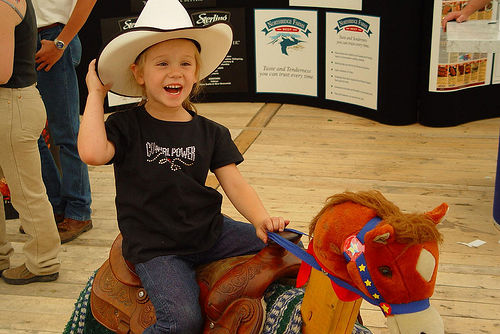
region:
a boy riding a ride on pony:
[62, 1, 471, 332]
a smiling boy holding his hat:
[68, 1, 270, 196]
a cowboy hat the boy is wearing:
[91, 3, 236, 58]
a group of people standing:
[3, 0, 86, 285]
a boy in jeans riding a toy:
[73, 23, 438, 329]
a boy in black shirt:
[73, 22, 305, 324]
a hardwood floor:
[278, 138, 405, 183]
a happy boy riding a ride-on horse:
[56, 5, 460, 332]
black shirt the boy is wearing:
[106, 108, 231, 258]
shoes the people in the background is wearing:
[3, 208, 93, 298]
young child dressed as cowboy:
[76, 2, 285, 332]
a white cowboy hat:
[93, 0, 235, 105]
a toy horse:
[69, 191, 448, 331]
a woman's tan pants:
[2, 85, 63, 277]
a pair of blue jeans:
[33, 23, 95, 222]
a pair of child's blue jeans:
[130, 215, 265, 331]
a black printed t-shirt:
[103, 103, 243, 258]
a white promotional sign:
[252, 8, 319, 94]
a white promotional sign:
[322, 8, 380, 112]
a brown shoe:
[53, 213, 92, 240]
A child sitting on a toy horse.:
[80, 5, 447, 330]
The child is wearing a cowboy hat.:
[95, 0, 230, 105]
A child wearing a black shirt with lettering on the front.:
[105, 101, 225, 251]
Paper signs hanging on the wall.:
[251, 5, 376, 105]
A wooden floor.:
[195, 122, 495, 207]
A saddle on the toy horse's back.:
[90, 230, 295, 325]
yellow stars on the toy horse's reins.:
[345, 255, 391, 320]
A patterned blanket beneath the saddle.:
[260, 280, 300, 330]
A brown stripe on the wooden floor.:
[195, 96, 285, 181]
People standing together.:
[0, 0, 91, 283]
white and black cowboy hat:
[76, 3, 219, 96]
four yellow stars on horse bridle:
[353, 257, 395, 318]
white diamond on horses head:
[394, 233, 454, 290]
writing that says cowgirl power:
[106, 128, 209, 185]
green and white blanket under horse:
[251, 173, 396, 330]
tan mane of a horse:
[267, 177, 479, 254]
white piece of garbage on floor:
[456, 221, 493, 283]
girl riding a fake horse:
[1, 23, 495, 309]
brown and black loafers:
[0, 236, 62, 300]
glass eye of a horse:
[372, 253, 411, 286]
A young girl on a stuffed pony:
[146, 44, 418, 321]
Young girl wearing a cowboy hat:
[117, 3, 220, 140]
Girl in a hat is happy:
[135, 32, 225, 129]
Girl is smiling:
[143, 46, 210, 130]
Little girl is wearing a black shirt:
[107, 34, 234, 281]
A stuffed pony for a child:
[289, 169, 435, 327]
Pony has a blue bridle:
[258, 213, 435, 320]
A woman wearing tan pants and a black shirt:
[3, 0, 60, 273]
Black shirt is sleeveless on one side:
[1, 2, 41, 93]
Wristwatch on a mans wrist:
[41, 17, 68, 68]